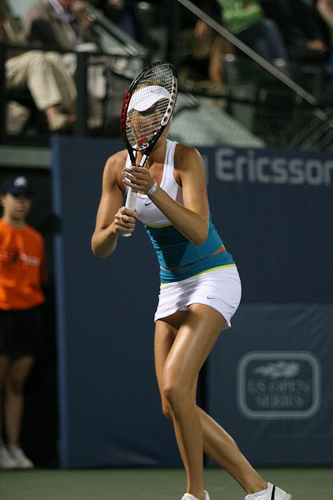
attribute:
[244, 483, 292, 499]
shoe — white, black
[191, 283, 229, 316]
symbol — small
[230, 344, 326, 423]
logo — white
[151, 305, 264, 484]
leg — tan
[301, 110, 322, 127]
ground — Green 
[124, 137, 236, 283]
shirt — blue, white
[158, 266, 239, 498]
leg — tan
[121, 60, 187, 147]
racket — black, red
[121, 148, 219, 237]
arm — tan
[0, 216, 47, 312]
shirt — red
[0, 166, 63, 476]
person — standing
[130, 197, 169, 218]
nike logo — On shirt 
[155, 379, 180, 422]
knees — bent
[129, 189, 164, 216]
nike — On shirt 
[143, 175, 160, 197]
band — around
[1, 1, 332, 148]
railing — black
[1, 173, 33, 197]
dark cap — Dark 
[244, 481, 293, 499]
foot — In the back 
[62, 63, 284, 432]
woman — playing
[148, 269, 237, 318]
skirt — white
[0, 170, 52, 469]
person — Standing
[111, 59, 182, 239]
tennis racquet — modern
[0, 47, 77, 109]
slacks — Khaki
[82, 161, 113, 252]
arm — tan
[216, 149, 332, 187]
letters — white